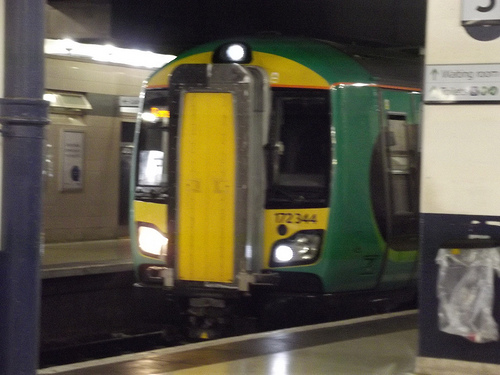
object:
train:
[125, 27, 420, 343]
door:
[171, 89, 243, 291]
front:
[128, 31, 391, 345]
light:
[222, 40, 251, 63]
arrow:
[429, 69, 441, 81]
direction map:
[423, 60, 497, 104]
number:
[273, 211, 284, 223]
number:
[309, 213, 320, 222]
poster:
[56, 126, 89, 194]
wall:
[41, 40, 161, 293]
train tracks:
[34, 319, 194, 374]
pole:
[1, 1, 54, 374]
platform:
[38, 311, 420, 372]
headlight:
[274, 243, 294, 261]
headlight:
[129, 222, 172, 258]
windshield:
[131, 89, 176, 197]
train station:
[0, 1, 499, 374]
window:
[382, 150, 418, 221]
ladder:
[370, 228, 418, 301]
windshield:
[267, 86, 332, 194]